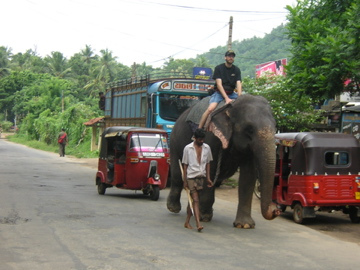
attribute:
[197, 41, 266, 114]
man — riding, wearing, walking, holding, barefoot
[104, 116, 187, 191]
taxi — here, red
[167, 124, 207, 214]
man — walking, carrying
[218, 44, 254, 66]
hat — black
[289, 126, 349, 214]
cab — red, here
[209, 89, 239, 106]
jeans — blue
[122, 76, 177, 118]
bus — blue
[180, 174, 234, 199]
shorts — brown, blue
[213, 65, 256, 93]
shirt — worn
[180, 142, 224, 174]
shirt — white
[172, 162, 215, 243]
stick — held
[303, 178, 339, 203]
light — tail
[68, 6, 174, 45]
sky — light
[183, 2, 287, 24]
wires — black